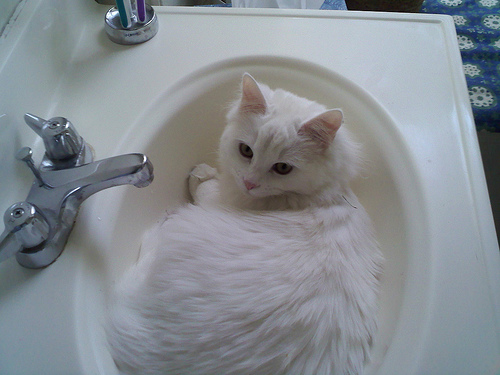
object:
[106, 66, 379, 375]
cat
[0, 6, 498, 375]
sink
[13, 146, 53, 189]
plunger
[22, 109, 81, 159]
valve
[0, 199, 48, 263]
valve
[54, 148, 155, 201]
faucet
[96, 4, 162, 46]
holder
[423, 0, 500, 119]
rug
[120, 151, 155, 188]
spigot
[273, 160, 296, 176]
eye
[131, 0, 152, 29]
toothbrush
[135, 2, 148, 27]
purple handle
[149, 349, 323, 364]
camera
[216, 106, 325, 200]
face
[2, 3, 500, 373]
bathroom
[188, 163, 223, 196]
paw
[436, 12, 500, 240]
edge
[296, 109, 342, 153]
ear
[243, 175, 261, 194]
nose